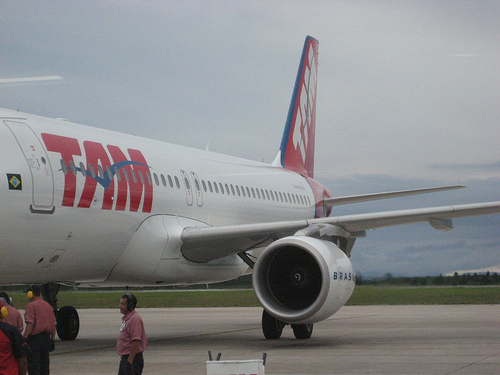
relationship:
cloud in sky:
[198, 34, 241, 96] [33, 9, 470, 238]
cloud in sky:
[334, 12, 383, 82] [3, 3, 498, 155]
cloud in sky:
[9, 50, 64, 107] [1, 0, 498, 271]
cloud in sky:
[418, 76, 458, 120] [1, 0, 498, 271]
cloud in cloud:
[334, 12, 383, 82] [418, 76, 458, 120]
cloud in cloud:
[198, 34, 241, 96] [418, 76, 458, 120]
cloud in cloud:
[9, 50, 64, 107] [418, 76, 458, 120]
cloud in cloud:
[123, 32, 158, 74] [418, 76, 458, 120]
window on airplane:
[170, 172, 182, 190] [11, 27, 492, 343]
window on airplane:
[292, 192, 303, 206] [11, 27, 492, 343]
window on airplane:
[104, 158, 114, 188] [11, 27, 492, 343]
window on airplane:
[57, 159, 72, 177] [11, 27, 492, 343]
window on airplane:
[251, 185, 260, 202] [11, 27, 492, 343]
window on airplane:
[165, 170, 174, 190] [11, 27, 492, 343]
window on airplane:
[95, 162, 108, 181] [11, 27, 492, 343]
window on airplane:
[47, 145, 80, 177] [11, 27, 492, 343]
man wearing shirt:
[103, 284, 163, 373] [110, 312, 140, 351]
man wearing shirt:
[16, 280, 58, 372] [18, 295, 59, 341]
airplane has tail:
[9, 10, 498, 368] [293, 26, 328, 170]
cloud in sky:
[435, 161, 498, 178] [383, 46, 439, 86]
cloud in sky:
[435, 161, 498, 178] [1, 0, 498, 271]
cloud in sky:
[198, 34, 241, 96] [28, 13, 336, 88]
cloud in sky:
[435, 161, 498, 178] [28, 13, 336, 88]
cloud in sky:
[334, 12, 383, 82] [399, 35, 440, 80]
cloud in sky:
[435, 161, 498, 178] [347, 19, 458, 166]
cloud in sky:
[198, 34, 241, 96] [1, 2, 499, 113]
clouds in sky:
[321, 35, 488, 165] [387, 65, 494, 132]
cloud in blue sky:
[435, 161, 498, 178] [312, 176, 498, 279]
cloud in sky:
[198, 34, 241, 96] [11, 7, 493, 122]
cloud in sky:
[334, 12, 383, 82] [11, 7, 493, 122]